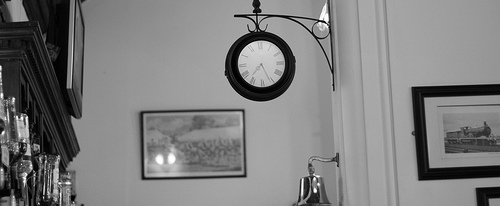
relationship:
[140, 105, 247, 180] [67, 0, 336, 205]
picture hanging on wall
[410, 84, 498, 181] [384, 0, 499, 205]
picture hanging on wall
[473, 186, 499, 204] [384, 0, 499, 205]
picture hanging on wall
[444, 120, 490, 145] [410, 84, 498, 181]
train shown in picture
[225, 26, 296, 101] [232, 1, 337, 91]
clock hanging on rod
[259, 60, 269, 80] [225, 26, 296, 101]
minute hand inside of clock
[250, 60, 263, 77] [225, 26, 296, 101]
hour hand inside of clock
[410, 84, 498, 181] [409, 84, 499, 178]
picture inside of frame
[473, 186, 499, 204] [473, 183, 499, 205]
picture inside of frame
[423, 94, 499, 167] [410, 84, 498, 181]
matte inside of picture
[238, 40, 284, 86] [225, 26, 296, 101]
roman numerals inside of clock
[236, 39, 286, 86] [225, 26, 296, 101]
face inside of clock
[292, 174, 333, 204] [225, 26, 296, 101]
bell beneath clock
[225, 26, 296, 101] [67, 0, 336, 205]
clock hanging on wall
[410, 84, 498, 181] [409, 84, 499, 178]
picture has frame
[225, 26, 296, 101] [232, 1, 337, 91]
clock hanging from rod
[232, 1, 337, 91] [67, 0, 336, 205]
rod mounted on wall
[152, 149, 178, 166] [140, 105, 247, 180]
light reflecting on picture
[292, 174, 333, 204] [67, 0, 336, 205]
bell hanging from wall